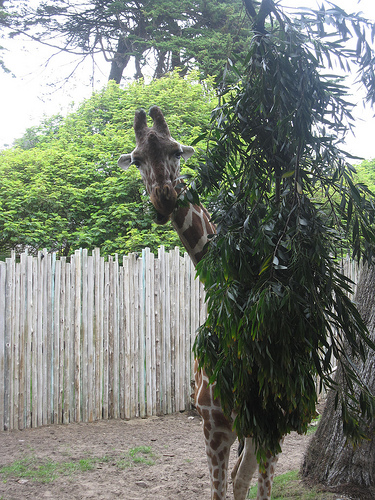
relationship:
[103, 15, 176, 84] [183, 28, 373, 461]
tree has branch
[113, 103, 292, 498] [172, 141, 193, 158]
giraffe has ear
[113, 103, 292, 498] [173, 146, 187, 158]
giraffe has eye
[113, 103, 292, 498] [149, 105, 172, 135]
giraffe has antlers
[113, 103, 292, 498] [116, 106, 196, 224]
giraffe has head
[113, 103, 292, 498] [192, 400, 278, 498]
giraffe has legs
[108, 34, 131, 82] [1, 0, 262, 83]
bark on tree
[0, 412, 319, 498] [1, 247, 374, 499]
ground in enclosure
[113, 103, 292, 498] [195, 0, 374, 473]
giraffe behind branch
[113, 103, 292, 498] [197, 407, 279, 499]
giraffe has legs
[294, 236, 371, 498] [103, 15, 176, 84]
bark of tree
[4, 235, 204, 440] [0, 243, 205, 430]
logs of fence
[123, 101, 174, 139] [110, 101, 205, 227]
antlers on head